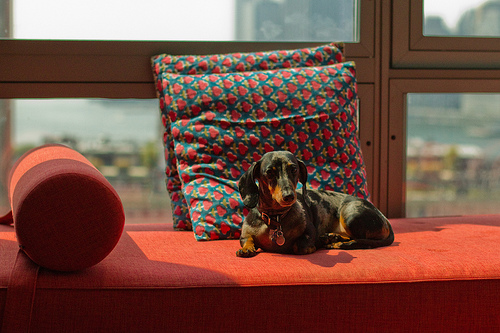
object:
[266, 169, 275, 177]
eyes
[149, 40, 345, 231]
pillow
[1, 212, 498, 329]
bed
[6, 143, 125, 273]
pillow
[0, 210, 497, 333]
couch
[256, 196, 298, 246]
dog collar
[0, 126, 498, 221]
city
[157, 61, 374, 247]
pillow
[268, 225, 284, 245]
tags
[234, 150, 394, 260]
dachshund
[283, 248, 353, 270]
shadow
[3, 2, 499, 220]
window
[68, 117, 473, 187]
view